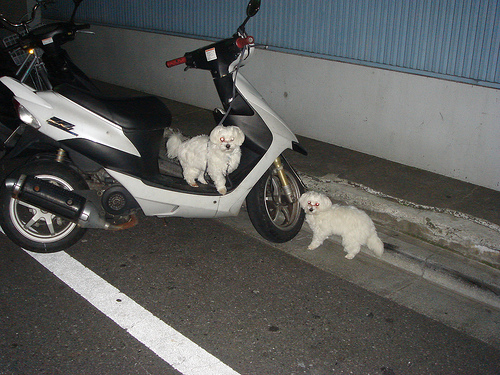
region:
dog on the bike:
[153, 85, 258, 191]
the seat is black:
[64, 67, 172, 126]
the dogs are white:
[174, 112, 352, 247]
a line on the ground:
[58, 266, 205, 366]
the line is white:
[63, 252, 210, 368]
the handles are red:
[153, 30, 308, 93]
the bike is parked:
[6, 15, 411, 301]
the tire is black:
[240, 170, 315, 267]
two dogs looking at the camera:
[181, 122, 434, 294]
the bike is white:
[36, 100, 307, 217]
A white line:
[120, 291, 247, 371]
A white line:
[131, 250, 213, 368]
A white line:
[91, 264, 188, 372]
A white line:
[71, 300, 176, 362]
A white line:
[36, 179, 205, 340]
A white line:
[2, 223, 164, 358]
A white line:
[186, 330, 233, 370]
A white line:
[134, 310, 218, 370]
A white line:
[59, 263, 146, 369]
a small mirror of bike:
[236, 0, 267, 25]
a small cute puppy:
[301, 192, 383, 280]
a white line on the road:
[58, 262, 238, 373]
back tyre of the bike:
[12, 170, 92, 243]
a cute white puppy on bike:
[166, 119, 250, 197]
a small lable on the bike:
[198, 49, 220, 67]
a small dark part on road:
[265, 310, 297, 338]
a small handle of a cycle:
[6, 7, 51, 29]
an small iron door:
[292, 7, 498, 77]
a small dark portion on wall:
[272, 63, 297, 109]